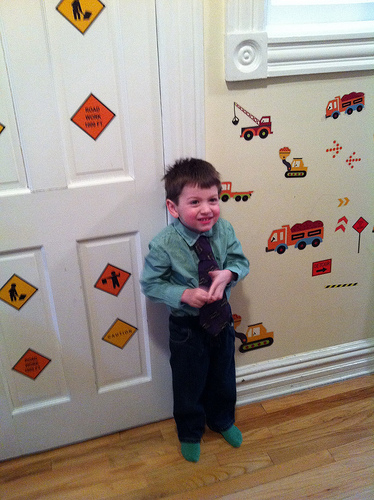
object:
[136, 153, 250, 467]
kid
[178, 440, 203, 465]
socks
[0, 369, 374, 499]
floor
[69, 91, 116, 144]
sticker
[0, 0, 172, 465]
door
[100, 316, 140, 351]
sticker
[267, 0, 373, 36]
window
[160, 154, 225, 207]
hair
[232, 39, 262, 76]
design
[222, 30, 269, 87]
corner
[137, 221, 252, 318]
shirt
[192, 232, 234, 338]
tie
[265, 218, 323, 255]
sticker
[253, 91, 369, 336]
wall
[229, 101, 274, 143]
sticker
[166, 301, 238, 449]
pants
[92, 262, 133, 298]
sticker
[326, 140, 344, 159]
arrow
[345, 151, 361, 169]
arrow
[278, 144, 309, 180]
sticker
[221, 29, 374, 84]
moulding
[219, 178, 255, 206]
sticker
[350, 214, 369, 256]
sticker